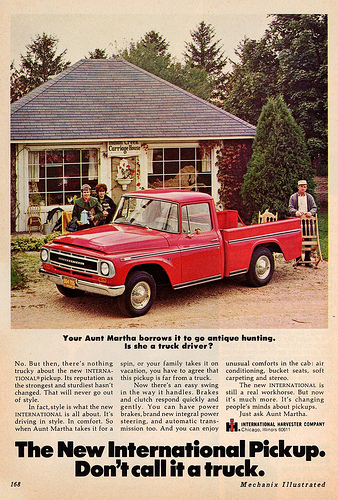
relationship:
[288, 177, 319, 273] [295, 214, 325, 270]
man holding chair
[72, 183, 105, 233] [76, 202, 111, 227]
lady are holding antiques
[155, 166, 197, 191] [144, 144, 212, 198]
carousel horse in window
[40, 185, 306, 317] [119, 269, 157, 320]
pickup truck has a tire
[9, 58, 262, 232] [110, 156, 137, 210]
antique store has a door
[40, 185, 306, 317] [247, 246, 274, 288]
pickup truck has a back wheel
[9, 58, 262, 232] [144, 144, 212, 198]
house has a window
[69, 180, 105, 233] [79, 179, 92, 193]
lady has gray hair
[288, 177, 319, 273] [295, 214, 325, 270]
man behind chair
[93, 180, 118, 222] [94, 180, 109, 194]
woman has red hair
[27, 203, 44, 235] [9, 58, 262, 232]
chair leaning against antique store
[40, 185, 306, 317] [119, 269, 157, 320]
pickup truck has a front tire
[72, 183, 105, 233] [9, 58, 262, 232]
lady are outside an antique shop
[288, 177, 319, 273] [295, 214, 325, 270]
shop owner loading h product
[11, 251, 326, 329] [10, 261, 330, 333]
gravel on dirt road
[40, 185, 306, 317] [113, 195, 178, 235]
pickup truck has a windshield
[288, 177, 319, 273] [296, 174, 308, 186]
man in a hat